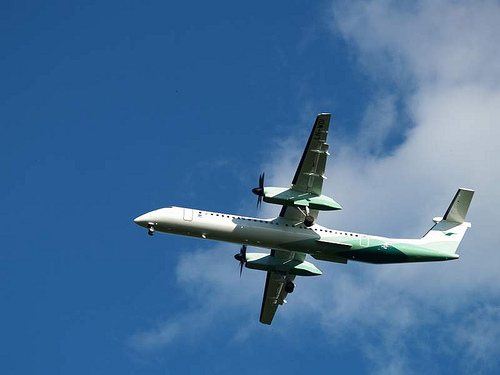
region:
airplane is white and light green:
[131, 111, 476, 325]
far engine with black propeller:
[235, 240, 320, 282]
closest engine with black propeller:
[252, 171, 343, 212]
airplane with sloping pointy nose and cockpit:
[132, 203, 177, 233]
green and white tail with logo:
[419, 185, 474, 259]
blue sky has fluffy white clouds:
[0, 0, 499, 373]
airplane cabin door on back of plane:
[357, 233, 369, 248]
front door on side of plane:
[182, 205, 192, 221]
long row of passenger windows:
[207, 208, 359, 239]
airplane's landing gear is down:
[144, 213, 314, 293]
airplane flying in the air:
[135, 110, 473, 325]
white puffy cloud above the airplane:
[128, 3, 498, 372]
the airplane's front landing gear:
[147, 224, 155, 239]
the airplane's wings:
[239, 112, 343, 322]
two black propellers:
[234, 175, 265, 272]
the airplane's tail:
[418, 187, 473, 259]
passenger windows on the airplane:
[198, 210, 359, 236]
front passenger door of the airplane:
[181, 205, 193, 221]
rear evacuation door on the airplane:
[360, 234, 368, 246]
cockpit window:
[164, 205, 173, 209]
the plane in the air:
[133, 113, 474, 325]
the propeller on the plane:
[250, 174, 265, 209]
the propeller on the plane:
[235, 243, 248, 277]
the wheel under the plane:
[147, 226, 154, 238]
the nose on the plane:
[132, 213, 146, 228]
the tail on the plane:
[419, 187, 476, 253]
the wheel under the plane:
[303, 214, 313, 227]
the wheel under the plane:
[285, 281, 295, 295]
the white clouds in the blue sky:
[0, 1, 497, 373]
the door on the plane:
[182, 208, 192, 221]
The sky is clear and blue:
[29, 24, 195, 138]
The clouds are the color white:
[406, 36, 497, 191]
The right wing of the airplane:
[235, 270, 302, 327]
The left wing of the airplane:
[278, 85, 355, 197]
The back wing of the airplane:
[418, 184, 483, 266]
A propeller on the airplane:
[249, 170, 269, 212]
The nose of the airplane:
[131, 195, 178, 237]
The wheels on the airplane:
[138, 224, 163, 241]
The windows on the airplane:
[182, 207, 380, 239]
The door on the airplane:
[180, 200, 200, 227]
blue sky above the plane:
[3, 53, 134, 149]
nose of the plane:
[116, 190, 168, 247]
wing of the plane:
[268, 99, 360, 219]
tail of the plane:
[414, 160, 494, 265]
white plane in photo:
[143, 123, 477, 330]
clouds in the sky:
[351, 113, 441, 190]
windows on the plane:
[191, 215, 300, 227]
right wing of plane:
[221, 241, 317, 341]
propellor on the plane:
[233, 165, 278, 220]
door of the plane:
[172, 200, 199, 242]